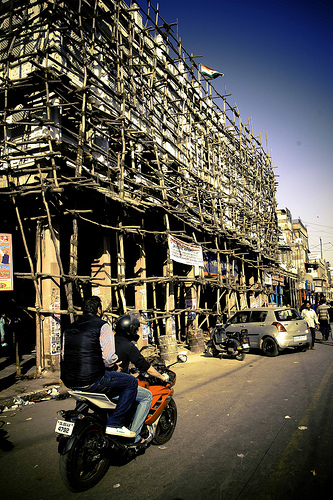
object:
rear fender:
[56, 428, 89, 454]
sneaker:
[105, 425, 135, 439]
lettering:
[57, 423, 69, 433]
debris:
[295, 422, 305, 431]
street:
[0, 319, 331, 497]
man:
[300, 301, 316, 351]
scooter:
[204, 324, 247, 360]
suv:
[208, 308, 313, 358]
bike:
[56, 352, 186, 491]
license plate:
[54, 418, 74, 437]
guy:
[60, 294, 136, 438]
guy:
[107, 316, 169, 449]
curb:
[1, 384, 62, 415]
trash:
[4, 383, 64, 414]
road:
[191, 358, 327, 494]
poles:
[209, 244, 331, 315]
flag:
[199, 63, 224, 81]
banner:
[166, 232, 204, 265]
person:
[315, 302, 328, 341]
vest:
[62, 314, 108, 388]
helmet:
[114, 313, 139, 344]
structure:
[22, 17, 304, 337]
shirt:
[317, 298, 332, 322]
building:
[0, 0, 278, 378]